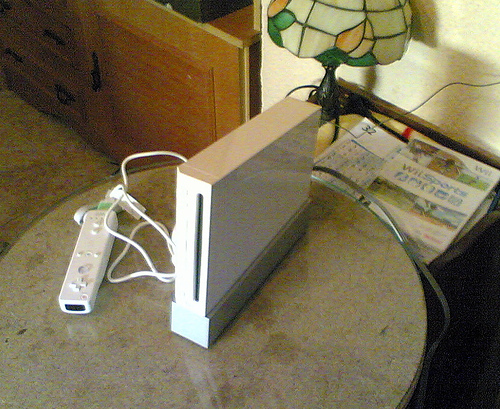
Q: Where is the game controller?
A: Beside the game.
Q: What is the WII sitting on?
A: Table.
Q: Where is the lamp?
A: Behind the WII.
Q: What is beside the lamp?
A: Calendar.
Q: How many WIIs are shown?
A: One.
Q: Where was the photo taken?
A: In a room.